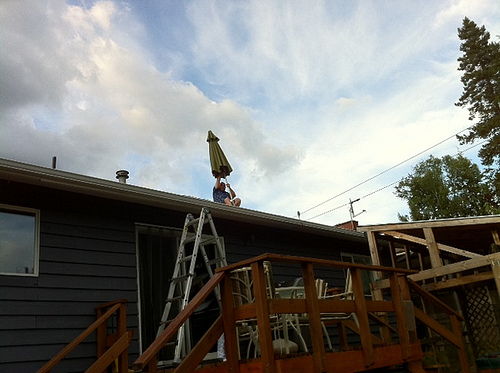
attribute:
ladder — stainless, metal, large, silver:
[143, 207, 249, 364]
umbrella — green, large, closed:
[202, 127, 237, 182]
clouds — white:
[3, 2, 130, 118]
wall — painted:
[2, 191, 155, 369]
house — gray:
[0, 158, 431, 369]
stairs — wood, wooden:
[62, 274, 242, 372]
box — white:
[264, 334, 303, 356]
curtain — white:
[352, 259, 375, 292]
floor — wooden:
[208, 342, 432, 373]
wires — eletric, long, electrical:
[290, 120, 498, 220]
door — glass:
[175, 236, 223, 361]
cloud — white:
[207, 97, 300, 175]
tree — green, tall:
[456, 15, 499, 171]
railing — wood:
[206, 256, 412, 346]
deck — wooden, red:
[89, 260, 460, 372]